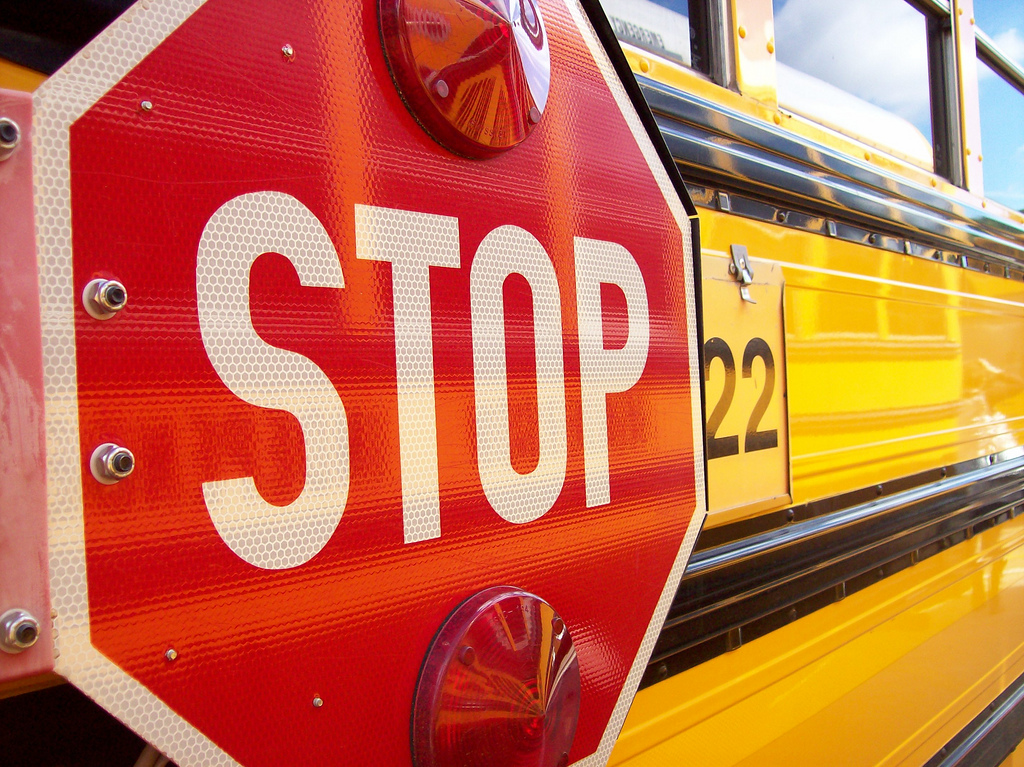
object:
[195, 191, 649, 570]
lettering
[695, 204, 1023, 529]
reflection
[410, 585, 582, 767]
light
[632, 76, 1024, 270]
paneling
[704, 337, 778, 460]
number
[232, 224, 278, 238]
pattern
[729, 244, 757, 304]
bolts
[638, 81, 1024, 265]
siding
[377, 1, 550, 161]
light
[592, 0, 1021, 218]
window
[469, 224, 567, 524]
letter o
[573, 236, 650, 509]
letter p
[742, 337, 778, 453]
number 2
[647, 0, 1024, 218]
blue sky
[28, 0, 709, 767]
reflecting paint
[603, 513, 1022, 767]
paint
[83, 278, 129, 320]
bolt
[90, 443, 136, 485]
bolt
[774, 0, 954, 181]
bus window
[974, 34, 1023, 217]
bus window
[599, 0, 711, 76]
bus window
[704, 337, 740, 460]
black number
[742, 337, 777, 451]
black number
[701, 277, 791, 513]
background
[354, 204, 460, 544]
white letter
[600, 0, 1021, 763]
side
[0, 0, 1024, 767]
bus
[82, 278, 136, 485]
bolts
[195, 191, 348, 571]
letter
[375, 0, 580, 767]
lights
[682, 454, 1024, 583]
strip